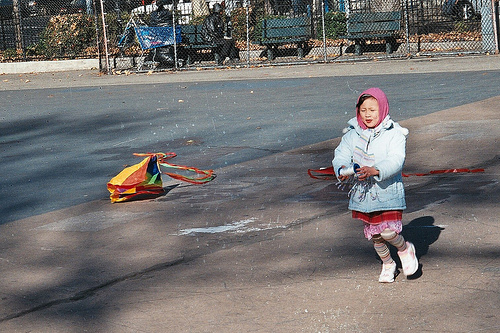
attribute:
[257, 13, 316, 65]
bench — green, wooden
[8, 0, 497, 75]
fence — chain link, tall, metal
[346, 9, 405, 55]
bench — green, wooden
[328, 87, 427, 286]
person — casting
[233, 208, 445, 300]
shadow — short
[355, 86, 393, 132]
head — woman's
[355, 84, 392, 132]
hood — pink, jacket's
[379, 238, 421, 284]
pair — white, shoes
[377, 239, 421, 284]
shoes — white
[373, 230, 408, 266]
leggings — striped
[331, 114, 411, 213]
coat — winter, light blue, blue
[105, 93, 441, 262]
leaves — dried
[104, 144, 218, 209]
kite — crashed, red, yellow, close, different colors, colorful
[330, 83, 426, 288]
child — walking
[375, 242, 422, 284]
sneakers — pair, child sized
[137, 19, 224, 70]
bench — green, wooden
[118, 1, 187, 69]
shopping cart — blue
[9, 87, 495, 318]
shadows — black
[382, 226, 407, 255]
stocking — striped, mult-color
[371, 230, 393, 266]
stocking — striped, mult-color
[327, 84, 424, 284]
girl — running, playing, standing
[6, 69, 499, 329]
road — grey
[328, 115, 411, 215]
jacket — blue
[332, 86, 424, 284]
she — trying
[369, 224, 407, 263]
socks — colored, brightly colored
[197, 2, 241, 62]
person — sitting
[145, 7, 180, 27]
garbage bag — black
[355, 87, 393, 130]
cap — pink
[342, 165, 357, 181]
thread — white